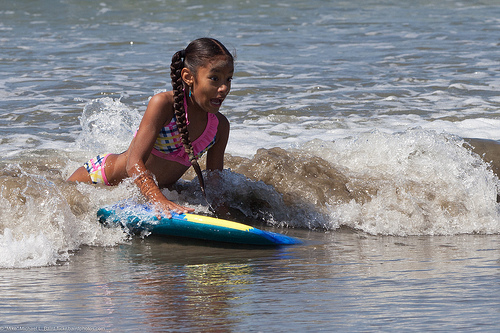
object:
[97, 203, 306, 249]
board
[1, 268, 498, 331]
water wave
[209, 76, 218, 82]
eye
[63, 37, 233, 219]
girl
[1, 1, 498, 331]
sea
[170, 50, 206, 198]
braid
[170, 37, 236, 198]
hair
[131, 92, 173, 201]
arm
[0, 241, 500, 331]
shore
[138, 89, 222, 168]
top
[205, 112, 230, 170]
arm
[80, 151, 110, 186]
bathing suit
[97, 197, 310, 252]
float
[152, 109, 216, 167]
bathingsuit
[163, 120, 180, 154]
stripes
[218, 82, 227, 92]
nose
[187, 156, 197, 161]
rubberband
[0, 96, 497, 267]
wave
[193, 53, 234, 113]
face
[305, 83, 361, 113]
foam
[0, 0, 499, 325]
beach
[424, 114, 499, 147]
sea foam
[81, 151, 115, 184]
bottom